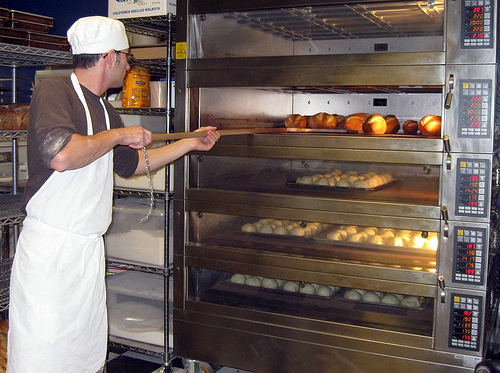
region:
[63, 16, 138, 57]
The man is wearing a chef hat.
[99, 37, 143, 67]
The chef is wearing glasses.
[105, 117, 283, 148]
The man is holding the stick.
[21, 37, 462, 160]
The man is baking bread.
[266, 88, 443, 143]
Bread in the oven.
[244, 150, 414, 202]
Bread dough cooking in the oven.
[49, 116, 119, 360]
The man is wearing a white apron.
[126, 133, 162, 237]
Chain hanging from the stick.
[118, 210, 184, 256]
Flower in the container.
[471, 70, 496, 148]
Buttons on the oven.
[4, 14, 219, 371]
A man in an apron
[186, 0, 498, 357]
A stack of ovens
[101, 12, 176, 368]
A set of metal shelves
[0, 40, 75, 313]
A set of metal shelves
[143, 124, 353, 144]
A large wooden paddle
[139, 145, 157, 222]
a small metal chain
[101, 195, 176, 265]
A large plastic container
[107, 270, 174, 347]
A large plastic container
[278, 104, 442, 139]
some bread in an oven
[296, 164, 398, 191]
some dough in an oven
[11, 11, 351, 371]
a person getting bread in the oven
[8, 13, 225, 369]
a person in front of the oven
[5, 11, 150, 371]
a person wearing an apron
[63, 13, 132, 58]
a white hat the person is wearing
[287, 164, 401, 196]
a uncooked bread in the oven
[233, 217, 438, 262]
trays of uncooked bread in the oven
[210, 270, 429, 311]
trays of uncooked bread in the oven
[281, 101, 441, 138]
cooked bread in the oven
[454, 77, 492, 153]
a control panel of the oven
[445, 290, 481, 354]
a control panel of the oven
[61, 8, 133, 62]
man's hat is white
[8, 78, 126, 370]
man wearing an apron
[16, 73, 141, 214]
man's shirt is brown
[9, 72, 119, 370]
man's apron is white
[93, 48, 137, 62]
man is wearing eye glasses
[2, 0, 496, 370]
man is getting bread from oven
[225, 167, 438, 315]
the bread is baking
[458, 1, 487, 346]
red and orange numbers on ovens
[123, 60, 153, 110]
orange bag on the rack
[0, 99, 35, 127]
bread on the rack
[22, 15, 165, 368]
this is a person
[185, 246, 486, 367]
this is an oven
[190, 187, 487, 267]
this is an oven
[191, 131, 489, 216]
this is an oven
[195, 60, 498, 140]
this is an oven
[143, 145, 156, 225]
this is a chain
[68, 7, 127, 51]
this is a chefs cap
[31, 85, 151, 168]
this is a hand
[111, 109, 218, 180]
this is a hand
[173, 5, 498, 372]
this is an oven